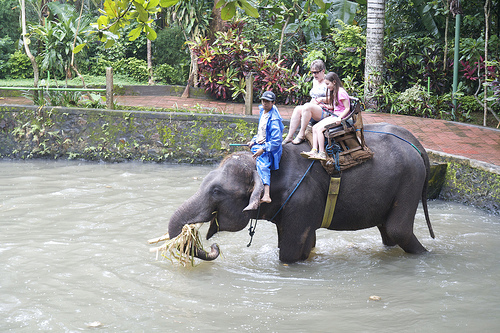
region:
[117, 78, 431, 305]
elephant in the water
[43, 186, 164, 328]
the water is murky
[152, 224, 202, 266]
some watery plant forms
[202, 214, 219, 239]
the mouth is open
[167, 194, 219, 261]
trunk of the elephant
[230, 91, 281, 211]
man on the elephant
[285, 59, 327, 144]
woman on the elephant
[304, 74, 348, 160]
girl on the elephant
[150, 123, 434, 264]
the elephant is gray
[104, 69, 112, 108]
post made of wood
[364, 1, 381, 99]
trunk of palm tree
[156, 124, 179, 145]
moss on the wall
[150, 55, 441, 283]
an elephant carries tourists around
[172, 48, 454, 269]
a tour guide travels with tourists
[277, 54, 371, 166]
a girl and her mother sit in a seat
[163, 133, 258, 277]
an elephant snacks on leaves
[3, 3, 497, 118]
a dense forest around a field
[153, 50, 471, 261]
an elephant carrying people takes a break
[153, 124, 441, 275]
an elephant bathes itself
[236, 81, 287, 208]
a man in blue rides an animal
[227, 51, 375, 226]
tourists are taken on a trip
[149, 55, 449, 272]
some people ride on the back of a large mammal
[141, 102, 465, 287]
this is an elephant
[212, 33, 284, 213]
a person riding an elephant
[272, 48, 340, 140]
a person riding an elephant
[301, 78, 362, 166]
a person riding an elephant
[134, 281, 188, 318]
the water is murkey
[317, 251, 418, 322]
the water is murkey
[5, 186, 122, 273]
the water is murkey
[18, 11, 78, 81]
this is a plant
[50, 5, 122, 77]
this is a plant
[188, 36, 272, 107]
this is a plant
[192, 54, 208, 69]
colorful leaf on bush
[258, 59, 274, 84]
colorful leaf on bush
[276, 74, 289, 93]
colorful leaf on bush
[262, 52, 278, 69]
colorful leaf on bush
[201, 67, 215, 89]
colorful leaf on bush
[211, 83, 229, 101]
colorful leaf on bush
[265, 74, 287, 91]
colorful leaf on bush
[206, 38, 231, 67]
colorful leaf on bush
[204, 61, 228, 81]
colorful leaf on bush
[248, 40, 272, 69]
colorful leaf on bush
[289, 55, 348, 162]
tourists riding an elephant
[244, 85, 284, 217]
man directing the elephant ride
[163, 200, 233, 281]
elephant pulling grasses into its mouth with its trunk